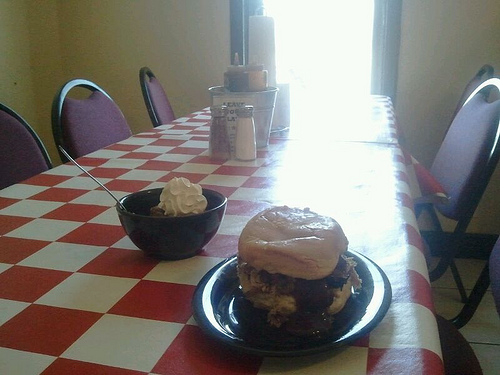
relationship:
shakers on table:
[184, 107, 299, 164] [5, 82, 446, 373]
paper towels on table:
[244, 10, 278, 87] [5, 82, 446, 373]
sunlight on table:
[284, 77, 393, 267] [5, 82, 446, 373]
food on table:
[225, 192, 355, 333] [7, 37, 457, 347]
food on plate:
[236, 204, 363, 335] [190, 324, 347, 343]